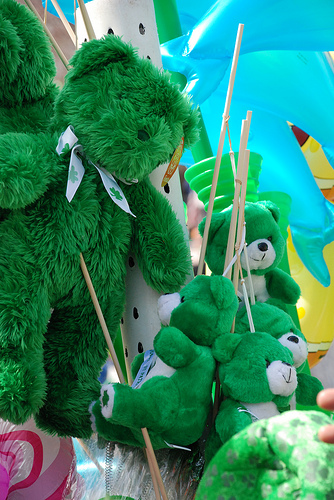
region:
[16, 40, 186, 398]
Green fluffy teddy bear with white ribbon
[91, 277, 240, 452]
green stuffed bear with shamrock on paw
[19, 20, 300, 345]
toy display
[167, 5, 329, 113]
blow up toy water animal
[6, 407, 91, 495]
pink inflated balloon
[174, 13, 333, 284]
blue blow up dolphin toys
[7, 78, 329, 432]
five stuffed green bear toys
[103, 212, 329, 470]
four identical green and white stuffed bears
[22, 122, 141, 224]
bow made from white ribbon with green shamrocks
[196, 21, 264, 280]
wooden dowel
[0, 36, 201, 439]
Large green fluffy teddy bear.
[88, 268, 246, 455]
Large green teddy bear.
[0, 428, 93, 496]
Large balloon with color printing on it.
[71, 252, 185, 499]
Wooden stick on a teddy bear.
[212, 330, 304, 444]
Green st patricks day teddy bear.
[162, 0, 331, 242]
Large section of a blue balloon.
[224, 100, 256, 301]
Large wooden sticks.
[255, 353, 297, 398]
Mouth of a green teddy bear.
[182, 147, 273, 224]
Plastic container on top of a teddy bear.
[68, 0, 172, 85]
large object near green teddy bears.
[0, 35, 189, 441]
a green fluffy teddy bear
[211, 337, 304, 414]
another green fluffy teddy bear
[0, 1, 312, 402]
six green teddy bears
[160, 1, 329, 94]
blue inflatable toys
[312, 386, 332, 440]
two fingers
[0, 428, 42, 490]
a red half circle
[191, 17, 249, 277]
sticks with the bears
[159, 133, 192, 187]
a tag hanging from the bear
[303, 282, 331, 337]
part of a yellow toy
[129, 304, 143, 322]
a green spot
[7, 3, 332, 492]
An outdoor image of stuff animals.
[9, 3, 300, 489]
A group of green teddy bears.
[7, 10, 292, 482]
A group of st. patrick's toy bears.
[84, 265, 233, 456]
A stuff bear with a green clover on his foot.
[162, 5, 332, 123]
A part of a blue whale.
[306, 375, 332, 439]
Two fingertips of a person.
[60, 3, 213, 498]
A white carrying poll.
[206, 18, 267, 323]
Some tan sticks holding the items.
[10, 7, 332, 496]
A scene of plush animals.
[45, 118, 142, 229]
A white ribbon.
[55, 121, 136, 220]
Shamrock and white bow on the bear.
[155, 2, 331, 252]
Blue inflatable toys in the background.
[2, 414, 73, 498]
Pink, red and white balloon.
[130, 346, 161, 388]
Blue bow on the toy.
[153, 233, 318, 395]
Bears have white snout.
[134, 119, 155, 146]
Small black nose on the green bear.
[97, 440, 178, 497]
Springs on the toys.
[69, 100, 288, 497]
Wooden dowels on the toys.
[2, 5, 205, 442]
Green fuzzy bears.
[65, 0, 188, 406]
White holder with holes for the toys.